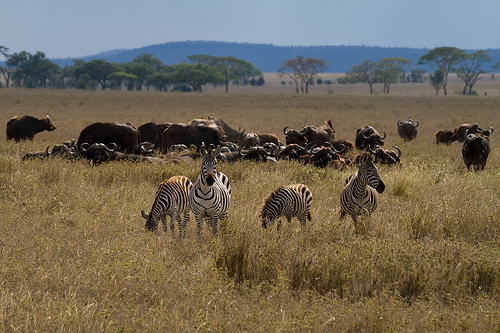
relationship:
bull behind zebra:
[2, 107, 463, 166] [338, 157, 380, 214]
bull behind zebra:
[2, 107, 463, 166] [261, 188, 311, 216]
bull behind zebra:
[2, 107, 463, 166] [191, 161, 238, 221]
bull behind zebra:
[2, 107, 463, 166] [146, 185, 193, 222]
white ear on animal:
[197, 141, 209, 157] [188, 141, 236, 237]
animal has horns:
[343, 108, 446, 163] [339, 118, 404, 150]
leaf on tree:
[158, 70, 161, 72] [108, 60, 158, 88]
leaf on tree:
[192, 67, 193, 69] [108, 60, 158, 88]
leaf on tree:
[103, 71, 107, 74] [108, 60, 158, 88]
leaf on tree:
[119, 71, 124, 76] [108, 60, 158, 88]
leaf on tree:
[151, 64, 153, 66] [108, 60, 158, 88]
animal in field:
[341, 156, 386, 227] [4, 80, 495, 331]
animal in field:
[262, 181, 312, 231] [4, 80, 495, 331]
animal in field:
[188, 141, 230, 233] [4, 80, 495, 331]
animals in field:
[139, 172, 194, 240] [4, 80, 495, 331]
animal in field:
[394, 115, 422, 143] [4, 80, 495, 331]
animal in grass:
[188, 141, 236, 237] [0, 84, 500, 331]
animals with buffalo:
[139, 172, 194, 240] [461, 124, 491, 169]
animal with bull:
[188, 141, 236, 237] [2, 107, 57, 145]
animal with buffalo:
[258, 181, 318, 231] [396, 120, 419, 140]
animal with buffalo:
[339, 151, 386, 223] [81, 121, 140, 152]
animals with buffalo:
[139, 172, 194, 240] [161, 124, 217, 149]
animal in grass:
[258, 181, 318, 231] [227, 222, 497, 297]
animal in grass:
[339, 151, 386, 223] [0, 84, 500, 331]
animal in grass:
[258, 181, 318, 231] [0, 84, 500, 331]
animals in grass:
[139, 172, 194, 240] [0, 84, 500, 331]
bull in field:
[2, 107, 57, 145] [4, 80, 495, 331]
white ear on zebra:
[200, 141, 209, 154] [190, 142, 230, 234]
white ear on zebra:
[210, 142, 226, 157] [190, 142, 230, 234]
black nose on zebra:
[204, 173, 216, 186] [190, 142, 230, 234]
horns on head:
[382, 132, 389, 144] [361, 132, 386, 147]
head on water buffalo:
[361, 132, 386, 147] [353, 121, 384, 155]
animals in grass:
[130, 152, 405, 246] [272, 239, 377, 279]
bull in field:
[75, 118, 139, 165] [4, 80, 495, 331]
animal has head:
[258, 181, 318, 231] [250, 197, 282, 240]